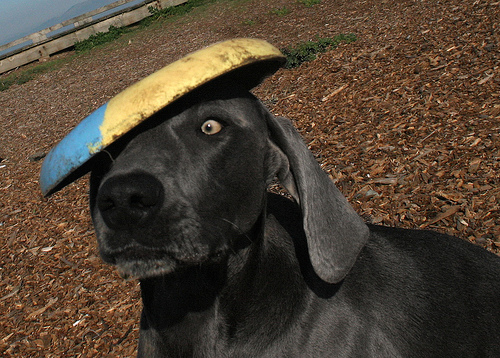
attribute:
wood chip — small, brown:
[434, 189, 459, 203]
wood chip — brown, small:
[322, 84, 348, 102]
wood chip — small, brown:
[445, 44, 460, 52]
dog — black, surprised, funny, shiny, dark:
[84, 81, 499, 357]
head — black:
[85, 92, 374, 285]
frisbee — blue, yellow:
[38, 37, 285, 201]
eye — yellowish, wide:
[198, 116, 226, 134]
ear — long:
[263, 107, 370, 283]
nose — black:
[96, 169, 164, 230]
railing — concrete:
[0, 1, 194, 74]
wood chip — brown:
[25, 296, 59, 324]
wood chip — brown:
[114, 323, 135, 345]